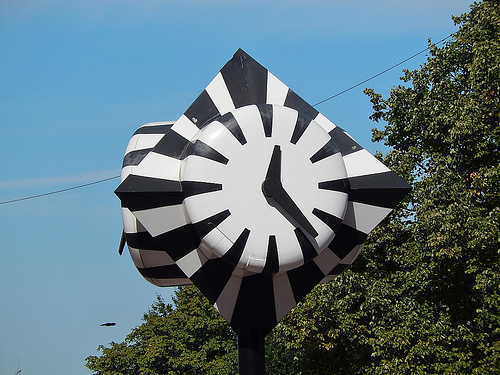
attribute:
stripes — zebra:
[122, 50, 412, 304]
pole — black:
[236, 335, 280, 370]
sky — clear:
[4, 1, 468, 370]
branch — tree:
[430, 245, 464, 274]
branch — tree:
[433, 300, 449, 327]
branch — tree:
[409, 270, 428, 293]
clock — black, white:
[179, 101, 348, 273]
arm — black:
[259, 140, 284, 194]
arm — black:
[260, 180, 318, 239]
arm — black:
[264, 185, 316, 239]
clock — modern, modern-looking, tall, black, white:
[180, 98, 362, 271]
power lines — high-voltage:
[11, 17, 481, 210]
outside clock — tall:
[118, 38, 417, 342]